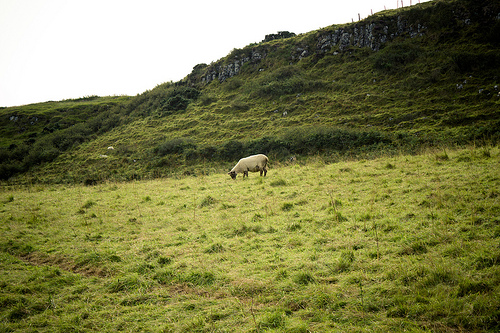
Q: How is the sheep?
A: Feeding.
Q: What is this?
A: A sheep.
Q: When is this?
A: Daytime.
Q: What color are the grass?
A: Green.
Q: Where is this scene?
A: In a meadow.